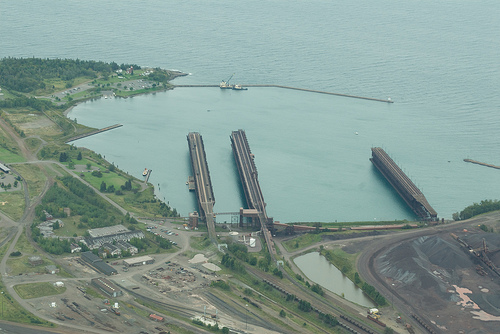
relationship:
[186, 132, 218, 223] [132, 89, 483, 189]
dock on water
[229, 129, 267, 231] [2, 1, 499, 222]
dock runs into water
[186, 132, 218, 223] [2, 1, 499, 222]
dock runs into water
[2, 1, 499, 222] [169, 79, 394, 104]
water surrounds runway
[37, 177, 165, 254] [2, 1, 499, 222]
trees near water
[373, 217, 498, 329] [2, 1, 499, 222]
quarry near water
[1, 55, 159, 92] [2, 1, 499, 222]
forest near water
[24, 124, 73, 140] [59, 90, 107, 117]
land near shore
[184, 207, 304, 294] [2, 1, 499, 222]
roadways near water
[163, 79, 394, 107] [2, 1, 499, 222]
barrier in water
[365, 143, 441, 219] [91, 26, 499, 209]
dock in water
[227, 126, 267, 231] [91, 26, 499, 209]
dock in water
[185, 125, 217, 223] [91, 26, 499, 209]
dock in water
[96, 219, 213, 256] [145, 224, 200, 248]
cars in cars